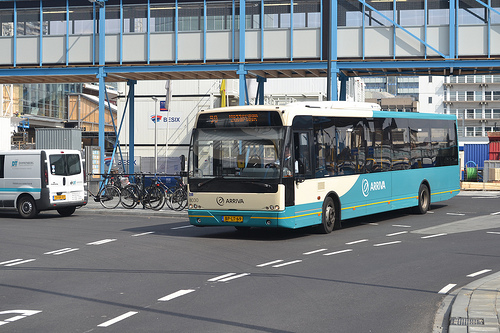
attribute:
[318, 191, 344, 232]
wheel — round, black, inflated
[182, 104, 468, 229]
bus — blue, white, large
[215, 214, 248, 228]
license plate — yellow, small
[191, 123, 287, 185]
windshield — clear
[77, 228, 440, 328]
stripes — white, broken, painted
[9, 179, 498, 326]
road — grey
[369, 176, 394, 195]
writing — white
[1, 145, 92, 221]
truck — white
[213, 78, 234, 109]
pole — yellow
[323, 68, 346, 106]
pole — blue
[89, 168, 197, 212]
bikes — parked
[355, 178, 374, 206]
logo — white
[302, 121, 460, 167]
window — large, tinted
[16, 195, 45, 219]
wheel — black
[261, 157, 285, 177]
steering wheel — black